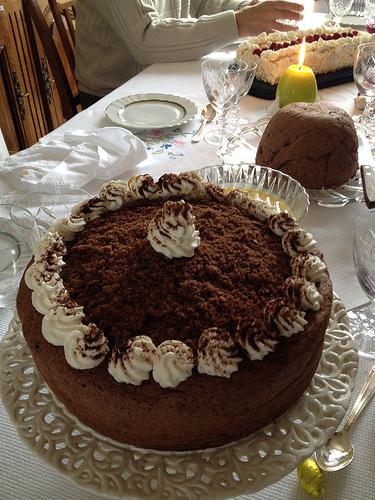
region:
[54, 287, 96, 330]
Brown crumbles on a cake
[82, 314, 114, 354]
Brown crumbles on a cake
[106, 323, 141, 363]
Brown crumbles on a cake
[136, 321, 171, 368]
Brown crumbles on a cake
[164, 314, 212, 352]
Brown crumbles on a cake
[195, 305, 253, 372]
Brown crumbles on a cake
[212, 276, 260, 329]
Brown crumbles on a cake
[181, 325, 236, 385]
White icing on a cake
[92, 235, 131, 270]
Brown crumbles on a cake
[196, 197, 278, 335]
Brown crumbles on a cake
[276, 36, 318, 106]
A bright green candle.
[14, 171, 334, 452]
A chocolate cake with whip cream on top.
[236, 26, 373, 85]
A cake with raspberries on top.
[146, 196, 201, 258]
Whip cream in the middle of the cake.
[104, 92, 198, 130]
Empty white plate.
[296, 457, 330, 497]
Chocolate egg in a foil wrapper.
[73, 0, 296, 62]
Persons arm near a candle.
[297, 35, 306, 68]
Flame on top of a candle.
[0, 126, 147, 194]
A linen napkin left on the table.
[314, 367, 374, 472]
Silver spoon on the table.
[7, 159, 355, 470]
A round chocolate desert.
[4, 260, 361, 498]
A round white serving plate.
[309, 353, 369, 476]
A silver spoon beside the plate.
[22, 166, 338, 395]
White decorative icing around the top of the cake.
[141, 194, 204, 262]
White icing in the center of the cake.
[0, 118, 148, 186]
A white napkin laying on the table.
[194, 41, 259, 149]
Two clear glasses to drink out of.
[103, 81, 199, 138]
A small round white serving plate.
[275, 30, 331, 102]
A candle that is burning.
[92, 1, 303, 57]
The person's right arm.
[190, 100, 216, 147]
a silver spoon on the table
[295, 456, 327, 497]
a small chocolate egg wrapped in gold foil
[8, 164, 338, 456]
a chocolate cake with vanilla frosting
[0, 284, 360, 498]
a decorative plate that holds the cake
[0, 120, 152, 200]
a crumpled up napkin on the table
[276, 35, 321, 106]
a lime green lit candle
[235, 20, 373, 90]
a rectangular cake with raspberries on top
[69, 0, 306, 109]
a person sitting at the table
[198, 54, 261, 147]
empty glasses on the table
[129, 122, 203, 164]
floral embroidery on the table cloth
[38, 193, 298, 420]
Cake is brown color.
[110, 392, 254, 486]
Cake is in plate.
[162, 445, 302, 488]
Plate is white color.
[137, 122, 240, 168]
Table cloth is white color.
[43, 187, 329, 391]
Cake is round shape.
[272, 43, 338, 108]
Candle is yellow color.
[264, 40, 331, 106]
Candle is on.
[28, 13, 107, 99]
Chair is brown color.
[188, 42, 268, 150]
Glass is in table.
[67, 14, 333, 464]
Three cakes are in table.